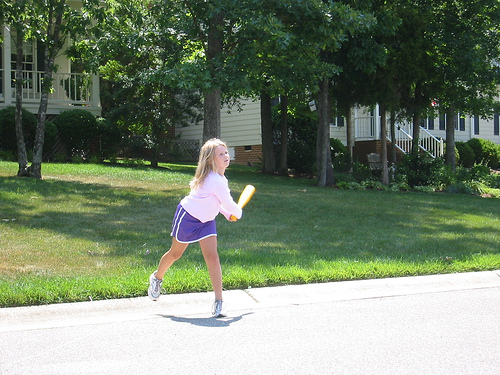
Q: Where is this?
A: This is at the lawn.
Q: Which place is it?
A: It is a lawn.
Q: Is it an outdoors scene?
A: Yes, it is outdoors.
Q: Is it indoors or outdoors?
A: It is outdoors.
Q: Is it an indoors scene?
A: No, it is outdoors.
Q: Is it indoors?
A: No, it is outdoors.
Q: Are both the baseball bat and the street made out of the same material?
A: No, the baseball bat is made of plastic and the street is made of concrete.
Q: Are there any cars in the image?
A: No, there are no cars.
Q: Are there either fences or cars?
A: No, there are no cars or fences.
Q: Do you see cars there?
A: No, there are no cars.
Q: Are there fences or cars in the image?
A: No, there are no cars or fences.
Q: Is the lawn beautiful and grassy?
A: Yes, the lawn is beautiful and grassy.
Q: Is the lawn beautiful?
A: Yes, the lawn is beautiful.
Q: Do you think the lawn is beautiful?
A: Yes, the lawn is beautiful.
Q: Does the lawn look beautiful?
A: Yes, the lawn is beautiful.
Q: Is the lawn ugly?
A: No, the lawn is beautiful.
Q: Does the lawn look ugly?
A: No, the lawn is beautiful.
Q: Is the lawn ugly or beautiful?
A: The lawn is beautiful.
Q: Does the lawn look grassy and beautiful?
A: Yes, the lawn is grassy and beautiful.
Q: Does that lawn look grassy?
A: Yes, the lawn is grassy.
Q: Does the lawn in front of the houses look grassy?
A: Yes, the lawn is grassy.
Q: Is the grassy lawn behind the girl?
A: Yes, the lawn is behind the girl.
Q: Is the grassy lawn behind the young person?
A: Yes, the lawn is behind the girl.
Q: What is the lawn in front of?
A: The lawn is in front of the houses.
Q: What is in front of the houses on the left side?
A: The lawn is in front of the houses.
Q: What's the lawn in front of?
A: The lawn is in front of the houses.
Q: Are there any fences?
A: No, there are no fences.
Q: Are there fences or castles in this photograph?
A: No, there are no fences or castles.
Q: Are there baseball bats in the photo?
A: Yes, there is a baseball bat.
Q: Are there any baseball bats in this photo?
A: Yes, there is a baseball bat.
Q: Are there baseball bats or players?
A: Yes, there is a baseball bat.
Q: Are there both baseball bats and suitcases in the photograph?
A: No, there is a baseball bat but no suitcases.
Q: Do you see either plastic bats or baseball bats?
A: Yes, there is a plastic baseball bat.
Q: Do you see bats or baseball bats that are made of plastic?
A: Yes, the baseball bat is made of plastic.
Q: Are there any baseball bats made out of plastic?
A: Yes, there is a baseball bat that is made of plastic.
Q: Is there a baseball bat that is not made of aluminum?
A: Yes, there is a baseball bat that is made of plastic.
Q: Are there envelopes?
A: No, there are no envelopes.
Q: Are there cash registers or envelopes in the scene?
A: No, there are no envelopes or cash registers.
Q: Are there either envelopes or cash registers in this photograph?
A: No, there are no envelopes or cash registers.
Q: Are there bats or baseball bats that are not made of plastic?
A: No, there is a baseball bat but it is made of plastic.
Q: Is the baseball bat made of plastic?
A: Yes, the baseball bat is made of plastic.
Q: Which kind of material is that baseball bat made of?
A: The baseball bat is made of plastic.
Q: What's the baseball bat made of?
A: The baseball bat is made of plastic.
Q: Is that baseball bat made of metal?
A: No, the baseball bat is made of plastic.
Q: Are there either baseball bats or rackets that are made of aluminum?
A: No, there is a baseball bat but it is made of plastic.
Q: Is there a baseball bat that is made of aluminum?
A: No, there is a baseball bat but it is made of plastic.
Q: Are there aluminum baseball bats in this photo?
A: No, there is a baseball bat but it is made of plastic.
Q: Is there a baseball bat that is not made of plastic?
A: No, there is a baseball bat but it is made of plastic.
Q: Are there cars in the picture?
A: No, there are no cars.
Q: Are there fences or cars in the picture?
A: No, there are no cars or fences.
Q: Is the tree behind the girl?
A: Yes, the tree is behind the girl.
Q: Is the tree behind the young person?
A: Yes, the tree is behind the girl.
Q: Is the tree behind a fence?
A: No, the tree is behind the girl.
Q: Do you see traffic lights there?
A: No, there are no traffic lights.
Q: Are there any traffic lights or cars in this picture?
A: No, there are no traffic lights or cars.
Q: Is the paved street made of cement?
A: Yes, the street is made of cement.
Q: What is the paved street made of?
A: The street is made of cement.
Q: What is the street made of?
A: The street is made of concrete.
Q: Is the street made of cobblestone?
A: No, the street is made of cement.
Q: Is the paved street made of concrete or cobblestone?
A: The street is made of concrete.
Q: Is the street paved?
A: Yes, the street is paved.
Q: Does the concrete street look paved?
A: Yes, the street is paved.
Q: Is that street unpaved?
A: No, the street is paved.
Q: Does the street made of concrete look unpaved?
A: No, the street is paved.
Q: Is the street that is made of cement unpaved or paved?
A: The street is paved.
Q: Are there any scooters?
A: No, there are no scooters.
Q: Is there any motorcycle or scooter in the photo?
A: No, there are no scooters or motorcycles.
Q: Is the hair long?
A: Yes, the hair is long.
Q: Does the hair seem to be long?
A: Yes, the hair is long.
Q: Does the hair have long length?
A: Yes, the hair is long.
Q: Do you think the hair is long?
A: Yes, the hair is long.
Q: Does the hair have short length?
A: No, the hair is long.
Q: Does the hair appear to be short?
A: No, the hair is long.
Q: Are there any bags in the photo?
A: No, there are no bags.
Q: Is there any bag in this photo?
A: No, there are no bags.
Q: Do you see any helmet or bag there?
A: No, there are no bags or helmets.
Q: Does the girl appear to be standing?
A: Yes, the girl is standing.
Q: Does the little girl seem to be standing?
A: Yes, the girl is standing.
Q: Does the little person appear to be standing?
A: Yes, the girl is standing.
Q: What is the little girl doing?
A: The girl is standing.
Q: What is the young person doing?
A: The girl is standing.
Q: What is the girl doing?
A: The girl is standing.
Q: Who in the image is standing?
A: The girl is standing.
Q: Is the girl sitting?
A: No, the girl is standing.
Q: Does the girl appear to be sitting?
A: No, the girl is standing.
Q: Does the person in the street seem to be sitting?
A: No, the girl is standing.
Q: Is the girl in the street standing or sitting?
A: The girl is standing.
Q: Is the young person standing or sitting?
A: The girl is standing.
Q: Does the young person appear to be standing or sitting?
A: The girl is standing.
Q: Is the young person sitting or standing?
A: The girl is standing.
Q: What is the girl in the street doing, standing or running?
A: The girl is standing.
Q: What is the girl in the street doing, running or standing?
A: The girl is standing.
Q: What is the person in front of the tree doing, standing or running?
A: The girl is standing.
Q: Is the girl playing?
A: Yes, the girl is playing.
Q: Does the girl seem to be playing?
A: Yes, the girl is playing.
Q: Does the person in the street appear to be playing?
A: Yes, the girl is playing.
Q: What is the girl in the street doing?
A: The girl is playing.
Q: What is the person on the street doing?
A: The girl is playing.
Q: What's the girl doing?
A: The girl is playing.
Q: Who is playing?
A: The girl is playing.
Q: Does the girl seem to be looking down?
A: No, the girl is playing.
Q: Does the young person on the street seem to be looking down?
A: No, the girl is playing.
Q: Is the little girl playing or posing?
A: The girl is playing.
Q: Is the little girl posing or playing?
A: The girl is playing.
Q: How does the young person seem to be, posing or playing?
A: The girl is playing.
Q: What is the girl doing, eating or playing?
A: The girl is playing.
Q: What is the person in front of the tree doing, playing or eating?
A: The girl is playing.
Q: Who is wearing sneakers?
A: The girl is wearing sneakers.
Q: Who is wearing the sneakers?
A: The girl is wearing sneakers.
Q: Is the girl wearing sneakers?
A: Yes, the girl is wearing sneakers.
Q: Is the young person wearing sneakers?
A: Yes, the girl is wearing sneakers.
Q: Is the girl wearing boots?
A: No, the girl is wearing sneakers.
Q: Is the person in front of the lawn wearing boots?
A: No, the girl is wearing sneakers.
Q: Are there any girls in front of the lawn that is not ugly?
A: Yes, there is a girl in front of the lawn.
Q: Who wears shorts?
A: The girl wears shorts.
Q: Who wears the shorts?
A: The girl wears shorts.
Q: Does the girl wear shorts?
A: Yes, the girl wears shorts.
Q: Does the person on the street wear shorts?
A: Yes, the girl wears shorts.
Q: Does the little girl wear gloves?
A: No, the girl wears shorts.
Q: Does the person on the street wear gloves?
A: No, the girl wears shorts.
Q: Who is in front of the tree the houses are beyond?
A: The girl is in front of the tree.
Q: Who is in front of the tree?
A: The girl is in front of the tree.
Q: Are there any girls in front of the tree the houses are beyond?
A: Yes, there is a girl in front of the tree.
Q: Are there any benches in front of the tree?
A: No, there is a girl in front of the tree.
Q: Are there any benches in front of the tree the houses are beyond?
A: No, there is a girl in front of the tree.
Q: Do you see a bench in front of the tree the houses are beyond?
A: No, there is a girl in front of the tree.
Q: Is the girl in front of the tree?
A: Yes, the girl is in front of the tree.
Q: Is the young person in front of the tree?
A: Yes, the girl is in front of the tree.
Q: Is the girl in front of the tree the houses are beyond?
A: Yes, the girl is in front of the tree.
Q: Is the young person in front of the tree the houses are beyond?
A: Yes, the girl is in front of the tree.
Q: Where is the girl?
A: The girl is in the street.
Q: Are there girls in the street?
A: Yes, there is a girl in the street.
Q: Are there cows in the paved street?
A: No, there is a girl in the street.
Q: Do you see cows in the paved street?
A: No, there is a girl in the street.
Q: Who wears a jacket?
A: The girl wears a jacket.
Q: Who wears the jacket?
A: The girl wears a jacket.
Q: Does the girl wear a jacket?
A: Yes, the girl wears a jacket.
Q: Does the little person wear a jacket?
A: Yes, the girl wears a jacket.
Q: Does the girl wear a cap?
A: No, the girl wears a jacket.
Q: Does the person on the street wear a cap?
A: No, the girl wears a jacket.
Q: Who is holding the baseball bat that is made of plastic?
A: The girl is holding the baseball bat.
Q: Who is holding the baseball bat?
A: The girl is holding the baseball bat.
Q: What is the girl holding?
A: The girl is holding the baseball bat.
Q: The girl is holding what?
A: The girl is holding the baseball bat.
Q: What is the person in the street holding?
A: The girl is holding the baseball bat.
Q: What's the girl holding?
A: The girl is holding the baseball bat.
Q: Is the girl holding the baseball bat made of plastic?
A: Yes, the girl is holding the baseball bat.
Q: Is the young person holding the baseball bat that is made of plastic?
A: Yes, the girl is holding the baseball bat.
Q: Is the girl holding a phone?
A: No, the girl is holding the baseball bat.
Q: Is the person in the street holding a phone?
A: No, the girl is holding the baseball bat.